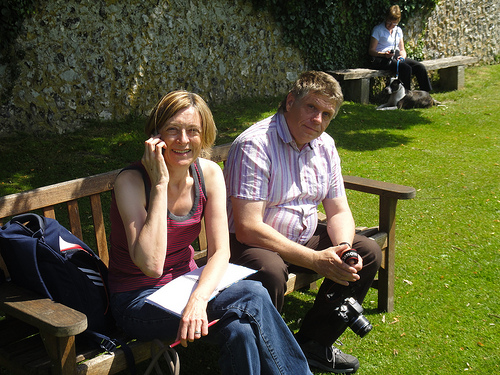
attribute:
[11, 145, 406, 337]
bench — wooden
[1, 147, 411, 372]
bench — wooden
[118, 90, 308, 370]
woman — smiling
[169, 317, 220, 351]
pencil — pink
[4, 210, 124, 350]
back pack — blue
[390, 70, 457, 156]
dog — black , white 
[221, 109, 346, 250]
shirt — striped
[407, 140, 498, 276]
grass — green, shirt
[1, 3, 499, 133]
wall — gray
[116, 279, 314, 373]
jeans — blue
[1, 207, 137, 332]
bag — blue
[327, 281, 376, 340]
camera — black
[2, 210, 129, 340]
backpack — blue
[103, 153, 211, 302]
tank top — pink and gray, striped